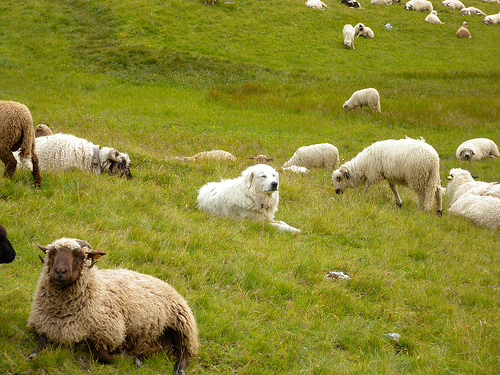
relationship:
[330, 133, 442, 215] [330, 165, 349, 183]
animal has ear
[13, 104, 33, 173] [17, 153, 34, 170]
tail has tip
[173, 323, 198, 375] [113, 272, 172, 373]
leg of a sheep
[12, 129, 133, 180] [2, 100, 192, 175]
sheep in green field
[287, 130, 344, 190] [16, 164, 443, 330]
gray sheep in green field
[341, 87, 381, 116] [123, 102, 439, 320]
gray sheep in green field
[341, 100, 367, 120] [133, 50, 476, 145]
gray sheep in green field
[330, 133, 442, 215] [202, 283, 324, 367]
animal in green field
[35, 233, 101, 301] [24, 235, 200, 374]
head of a animal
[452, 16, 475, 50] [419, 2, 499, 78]
animal in field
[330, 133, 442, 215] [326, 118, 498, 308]
animal in field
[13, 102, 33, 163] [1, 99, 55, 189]
tail on sheep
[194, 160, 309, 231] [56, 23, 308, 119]
animal in a field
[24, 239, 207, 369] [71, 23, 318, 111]
animal in a field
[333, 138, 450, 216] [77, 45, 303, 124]
animal in a field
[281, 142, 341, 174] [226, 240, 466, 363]
animal in a field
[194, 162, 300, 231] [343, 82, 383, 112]
animal in a field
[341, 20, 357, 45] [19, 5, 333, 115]
animal in a field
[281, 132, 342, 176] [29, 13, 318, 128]
animal in a field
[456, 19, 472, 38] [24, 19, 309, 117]
animal in a field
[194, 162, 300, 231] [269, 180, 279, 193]
animal has a nose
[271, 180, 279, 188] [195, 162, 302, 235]
nose belonging to dog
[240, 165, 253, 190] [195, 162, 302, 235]
right ear belonging to dog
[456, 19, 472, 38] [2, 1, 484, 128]
animal lying on hill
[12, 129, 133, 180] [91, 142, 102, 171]
sheep wearing collar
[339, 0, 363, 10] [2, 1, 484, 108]
sheep lying on hill